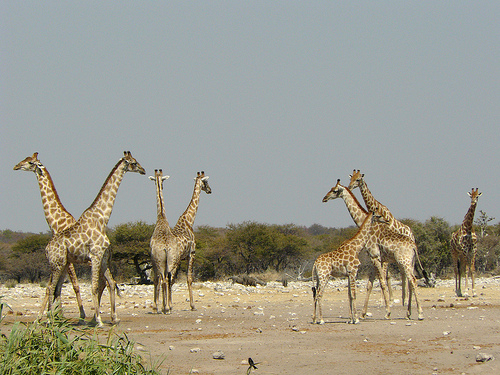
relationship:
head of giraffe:
[105, 141, 155, 190] [17, 125, 177, 362]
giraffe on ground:
[173, 164, 215, 292] [165, 297, 239, 324]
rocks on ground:
[240, 297, 278, 321] [203, 320, 339, 357]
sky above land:
[193, 38, 335, 167] [164, 270, 408, 356]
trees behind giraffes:
[208, 210, 291, 277] [14, 139, 430, 355]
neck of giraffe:
[88, 156, 135, 236] [39, 130, 164, 307]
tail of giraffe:
[305, 275, 332, 305] [294, 201, 406, 334]